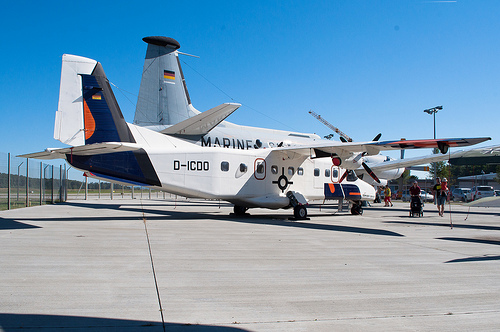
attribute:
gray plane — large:
[130, 36, 499, 187]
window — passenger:
[218, 158, 230, 173]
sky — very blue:
[199, 5, 493, 65]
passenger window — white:
[271, 166, 279, 173]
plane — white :
[91, 99, 377, 232]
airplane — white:
[18, 34, 494, 225]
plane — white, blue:
[15, 52, 492, 221]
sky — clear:
[1, 0, 499, 177]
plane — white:
[55, 52, 485, 210]